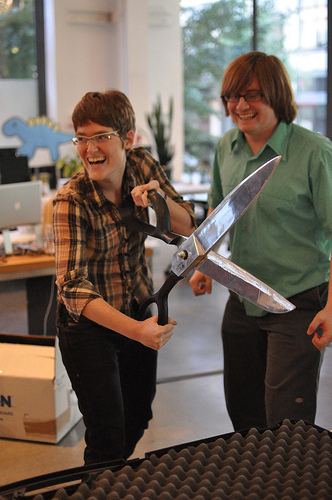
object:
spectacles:
[71, 130, 126, 146]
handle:
[138, 269, 179, 324]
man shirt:
[208, 122, 331, 317]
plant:
[145, 89, 175, 163]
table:
[0, 410, 332, 499]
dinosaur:
[170, 229, 199, 274]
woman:
[212, 51, 332, 426]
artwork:
[3, 116, 74, 162]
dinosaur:
[2, 117, 77, 162]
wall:
[2, 1, 183, 199]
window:
[180, 0, 329, 186]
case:
[2, 418, 331, 496]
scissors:
[119, 155, 296, 324]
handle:
[119, 181, 180, 243]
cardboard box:
[0, 334, 83, 445]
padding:
[0, 420, 332, 500]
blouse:
[52, 146, 195, 325]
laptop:
[0, 182, 40, 225]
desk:
[0, 223, 155, 335]